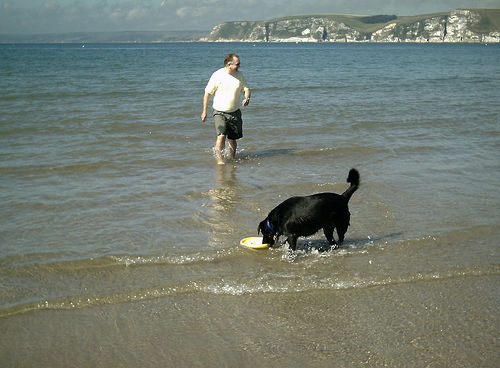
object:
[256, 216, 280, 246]
head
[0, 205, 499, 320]
waves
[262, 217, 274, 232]
collar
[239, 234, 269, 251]
disc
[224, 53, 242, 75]
head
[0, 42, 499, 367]
water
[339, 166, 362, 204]
tail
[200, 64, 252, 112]
shirt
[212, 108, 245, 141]
shorts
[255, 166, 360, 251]
dog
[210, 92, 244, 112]
belly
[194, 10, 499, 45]
rock cliff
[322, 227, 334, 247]
legs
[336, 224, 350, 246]
legs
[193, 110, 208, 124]
right hand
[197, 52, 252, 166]
man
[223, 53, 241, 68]
hair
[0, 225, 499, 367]
shore